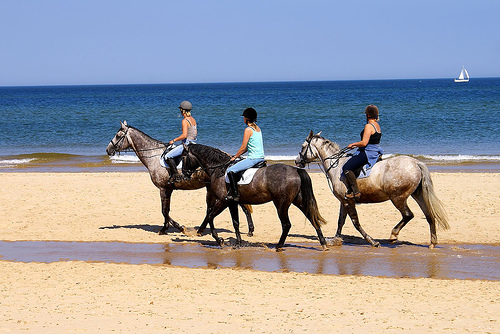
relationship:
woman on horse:
[226, 107, 266, 201] [179, 140, 329, 254]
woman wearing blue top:
[226, 107, 266, 201] [238, 122, 268, 161]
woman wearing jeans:
[160, 100, 200, 185] [166, 144, 193, 166]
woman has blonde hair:
[160, 100, 200, 185] [179, 109, 192, 115]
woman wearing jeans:
[235, 105, 274, 177] [228, 156, 248, 175]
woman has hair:
[235, 105, 274, 177] [243, 108, 256, 126]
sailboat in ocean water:
[453, 64, 471, 82] [0, 88, 500, 151]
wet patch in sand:
[10, 228, 432, 290] [15, 165, 426, 325]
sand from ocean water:
[15, 165, 426, 325] [0, 88, 500, 151]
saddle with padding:
[231, 154, 264, 185] [243, 170, 255, 180]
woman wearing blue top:
[226, 107, 266, 201] [246, 126, 265, 159]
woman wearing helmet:
[160, 100, 200, 185] [177, 98, 194, 113]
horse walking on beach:
[98, 66, 463, 291] [52, 155, 146, 195]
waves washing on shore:
[430, 148, 492, 167] [17, 162, 133, 183]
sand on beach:
[6, 230, 484, 290] [22, 31, 479, 296]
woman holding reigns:
[344, 104, 381, 199] [322, 144, 352, 173]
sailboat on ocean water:
[453, 65, 471, 82] [0, 88, 500, 151]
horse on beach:
[293, 130, 452, 252] [0, 168, 497, 331]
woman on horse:
[342, 104, 385, 200] [293, 130, 452, 252]